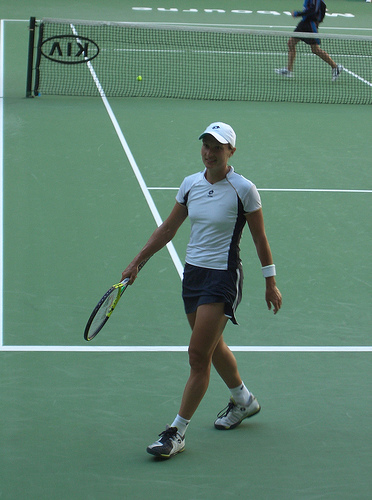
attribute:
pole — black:
[24, 16, 34, 97]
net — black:
[35, 15, 370, 110]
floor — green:
[3, 2, 369, 497]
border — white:
[41, 17, 371, 44]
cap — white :
[191, 112, 235, 149]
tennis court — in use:
[0, 0, 370, 499]